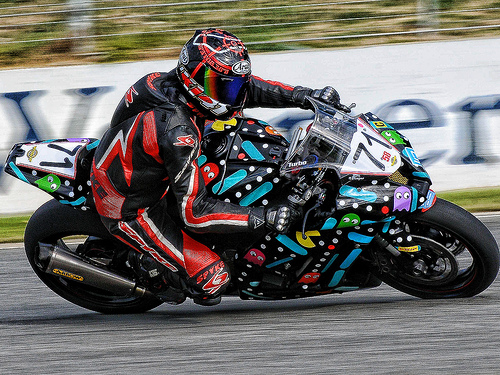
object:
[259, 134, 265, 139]
white dot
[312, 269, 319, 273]
dot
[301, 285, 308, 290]
dot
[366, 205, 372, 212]
dot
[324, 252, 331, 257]
dot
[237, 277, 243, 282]
white dot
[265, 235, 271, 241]
white dot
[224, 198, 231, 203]
white dot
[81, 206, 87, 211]
white dot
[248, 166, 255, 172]
white dot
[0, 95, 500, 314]
dot motorcycle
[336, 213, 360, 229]
ghost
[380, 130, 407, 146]
ghost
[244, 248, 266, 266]
ghost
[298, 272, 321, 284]
ghost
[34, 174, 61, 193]
ghost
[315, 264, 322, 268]
dot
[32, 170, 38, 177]
dot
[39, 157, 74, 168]
number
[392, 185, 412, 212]
ghost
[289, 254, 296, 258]
dot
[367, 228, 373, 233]
white dot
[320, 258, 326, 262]
dot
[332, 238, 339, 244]
dot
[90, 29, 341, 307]
motorcyclist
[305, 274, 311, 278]
dot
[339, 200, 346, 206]
dot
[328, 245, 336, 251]
dot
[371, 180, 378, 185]
dot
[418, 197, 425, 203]
dot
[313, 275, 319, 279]
dot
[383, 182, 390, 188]
dot